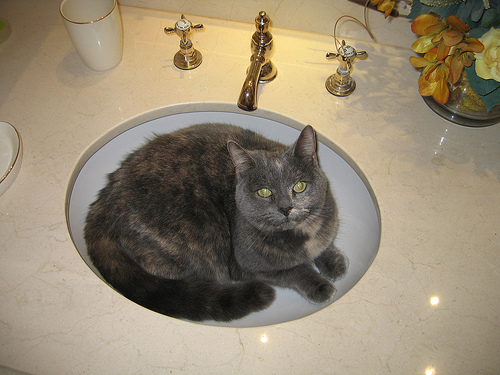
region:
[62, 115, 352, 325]
the cat is gray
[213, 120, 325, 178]
the cat's ears are sticking up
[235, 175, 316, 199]
the cat's eyes are open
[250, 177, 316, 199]
the cat's eyes are green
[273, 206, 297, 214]
the cat's nose is black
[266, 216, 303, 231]
the cat's mouth is closed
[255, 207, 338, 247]
the cat has whiskers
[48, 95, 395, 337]
the cat is curled up in the sink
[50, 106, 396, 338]
the sink is white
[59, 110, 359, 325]
the cat is looking at the camera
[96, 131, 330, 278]
this is a cat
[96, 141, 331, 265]
the cat is grey in color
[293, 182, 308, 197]
this is an eye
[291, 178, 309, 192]
the eye is green in color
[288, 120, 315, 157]
this is a ear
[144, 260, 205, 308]
this is a tail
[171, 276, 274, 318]
the tail is long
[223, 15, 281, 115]
this is a tap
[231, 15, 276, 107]
the tap is closed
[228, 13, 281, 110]
the tap is metalic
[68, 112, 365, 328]
the cat is in the sink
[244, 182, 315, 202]
the cat has green eyes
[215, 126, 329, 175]
the cat has pointy ears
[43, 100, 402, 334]
the sink is round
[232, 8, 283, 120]
the spigot is gold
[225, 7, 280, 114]
the spigot is shiny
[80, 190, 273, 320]
the cat's tail is long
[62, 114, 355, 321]
the cat is brown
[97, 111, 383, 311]
cat lying in sink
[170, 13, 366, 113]
gold faucets on sink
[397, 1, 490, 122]
vase of flowers on counter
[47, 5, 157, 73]
gold rimmed white glass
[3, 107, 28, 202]
white and gold rimmed soap dish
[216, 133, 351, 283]
gray cat with green eyes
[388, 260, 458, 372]
light bulbs reflecting on counter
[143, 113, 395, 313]
grey cat looking at camera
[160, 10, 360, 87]
hot and cold handles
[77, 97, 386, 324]
cat curled up in sink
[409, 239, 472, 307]
part of a sink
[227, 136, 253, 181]
ear of a cat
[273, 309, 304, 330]
edge of a cat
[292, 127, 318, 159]
edge of an ear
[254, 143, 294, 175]
head of a cat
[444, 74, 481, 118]
part of a container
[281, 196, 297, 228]
nose of a cat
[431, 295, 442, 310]
part of a light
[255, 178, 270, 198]
part of an eye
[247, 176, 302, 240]
face of a cat